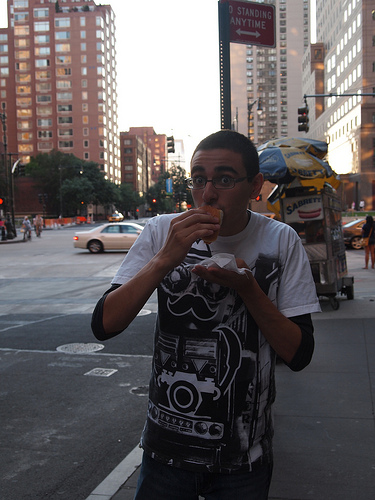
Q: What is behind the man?
A: Hot Dog stand.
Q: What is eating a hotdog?
A: The man.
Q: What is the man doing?
A: Eating hot dog.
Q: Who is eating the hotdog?
A: A man.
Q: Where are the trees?
A: Next to the building.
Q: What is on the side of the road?
A: Tall buildings.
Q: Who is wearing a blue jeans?
A: A young man.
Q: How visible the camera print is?
A: Very visible.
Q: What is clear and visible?
A: Short print.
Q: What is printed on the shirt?
A: Camera.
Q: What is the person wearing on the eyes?
A: Eyeglasses.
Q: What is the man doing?
A: Eating.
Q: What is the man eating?
A: Hot dog.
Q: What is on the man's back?
A: Shirts.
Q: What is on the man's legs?
A: Jeans.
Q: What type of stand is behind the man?
A: Hot dog.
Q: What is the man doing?
A: Eating.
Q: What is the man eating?
A: A hot dog.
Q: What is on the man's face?
A: Glasses.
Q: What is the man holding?
A: A hot dog.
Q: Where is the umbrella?
A: Behind the guy.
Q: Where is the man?
A: In the city.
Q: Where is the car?
A: On the street.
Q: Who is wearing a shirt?
A: The guy.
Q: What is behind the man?
A: Hot dog cart.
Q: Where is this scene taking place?
A: A large city street.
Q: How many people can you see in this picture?
A: 1.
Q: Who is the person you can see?
A: A young man.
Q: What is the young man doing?
A: Eating a hot dog.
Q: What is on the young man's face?
A: Glasses.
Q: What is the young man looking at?
A: The camera.